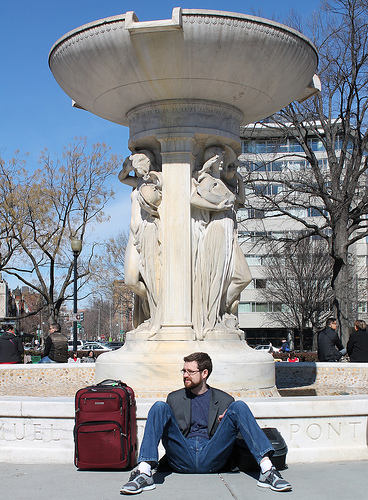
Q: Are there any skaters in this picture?
A: No, there are no skaters.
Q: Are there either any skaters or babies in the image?
A: No, there are no skaters or babies.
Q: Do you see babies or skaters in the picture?
A: No, there are no skaters or babies.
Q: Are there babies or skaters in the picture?
A: No, there are no skaters or babies.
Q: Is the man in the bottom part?
A: Yes, the man is in the bottom of the image.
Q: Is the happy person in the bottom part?
A: Yes, the man is in the bottom of the image.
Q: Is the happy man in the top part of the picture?
A: No, the man is in the bottom of the image.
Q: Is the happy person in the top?
A: No, the man is in the bottom of the image.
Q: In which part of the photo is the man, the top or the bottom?
A: The man is in the bottom of the image.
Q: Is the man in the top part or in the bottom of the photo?
A: The man is in the bottom of the image.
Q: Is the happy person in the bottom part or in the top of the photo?
A: The man is in the bottom of the image.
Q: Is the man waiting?
A: Yes, the man is waiting.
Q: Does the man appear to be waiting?
A: Yes, the man is waiting.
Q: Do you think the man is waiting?
A: Yes, the man is waiting.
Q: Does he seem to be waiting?
A: Yes, the man is waiting.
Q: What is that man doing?
A: The man is waiting.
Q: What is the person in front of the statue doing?
A: The man is waiting.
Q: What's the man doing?
A: The man is waiting.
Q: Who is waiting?
A: The man is waiting.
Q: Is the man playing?
A: No, the man is waiting.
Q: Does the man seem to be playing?
A: No, the man is waiting.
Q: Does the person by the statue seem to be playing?
A: No, the man is waiting.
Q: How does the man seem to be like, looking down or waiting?
A: The man is waiting.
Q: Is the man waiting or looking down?
A: The man is waiting.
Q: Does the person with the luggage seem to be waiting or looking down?
A: The man is waiting.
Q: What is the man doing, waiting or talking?
A: The man is waiting.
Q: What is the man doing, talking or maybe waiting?
A: The man is waiting.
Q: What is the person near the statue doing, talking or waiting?
A: The man is waiting.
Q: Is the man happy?
A: Yes, the man is happy.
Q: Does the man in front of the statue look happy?
A: Yes, the man is happy.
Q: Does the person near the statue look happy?
A: Yes, the man is happy.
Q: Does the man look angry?
A: No, the man is happy.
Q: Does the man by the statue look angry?
A: No, the man is happy.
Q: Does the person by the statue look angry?
A: No, the man is happy.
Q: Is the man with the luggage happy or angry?
A: The man is happy.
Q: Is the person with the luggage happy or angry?
A: The man is happy.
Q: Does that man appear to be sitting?
A: Yes, the man is sitting.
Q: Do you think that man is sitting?
A: Yes, the man is sitting.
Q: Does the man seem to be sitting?
A: Yes, the man is sitting.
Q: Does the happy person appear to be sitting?
A: Yes, the man is sitting.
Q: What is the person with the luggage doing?
A: The man is sitting.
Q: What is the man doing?
A: The man is sitting.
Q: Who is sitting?
A: The man is sitting.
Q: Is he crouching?
A: No, the man is sitting.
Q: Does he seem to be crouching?
A: No, the man is sitting.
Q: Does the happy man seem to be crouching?
A: No, the man is sitting.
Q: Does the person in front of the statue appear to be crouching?
A: No, the man is sitting.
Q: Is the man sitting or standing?
A: The man is sitting.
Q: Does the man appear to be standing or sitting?
A: The man is sitting.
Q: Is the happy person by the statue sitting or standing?
A: The man is sitting.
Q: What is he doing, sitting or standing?
A: The man is sitting.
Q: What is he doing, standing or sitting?
A: The man is sitting.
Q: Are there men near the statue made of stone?
A: Yes, there is a man near the statue.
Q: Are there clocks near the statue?
A: No, there is a man near the statue.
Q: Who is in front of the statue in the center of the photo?
A: The man is in front of the statue.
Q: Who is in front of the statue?
A: The man is in front of the statue.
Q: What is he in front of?
A: The man is in front of the statue.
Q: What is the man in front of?
A: The man is in front of the statue.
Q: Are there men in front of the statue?
A: Yes, there is a man in front of the statue.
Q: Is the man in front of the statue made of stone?
A: Yes, the man is in front of the statue.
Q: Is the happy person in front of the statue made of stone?
A: Yes, the man is in front of the statue.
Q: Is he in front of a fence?
A: No, the man is in front of the statue.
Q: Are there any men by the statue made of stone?
A: Yes, there is a man by the statue.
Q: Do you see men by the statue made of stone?
A: Yes, there is a man by the statue.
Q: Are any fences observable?
A: No, there are no fences.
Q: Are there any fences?
A: No, there are no fences.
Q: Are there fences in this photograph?
A: No, there are no fences.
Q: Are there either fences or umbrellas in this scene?
A: No, there are no fences or umbrellas.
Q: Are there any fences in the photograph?
A: No, there are no fences.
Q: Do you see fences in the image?
A: No, there are no fences.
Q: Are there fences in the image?
A: No, there are no fences.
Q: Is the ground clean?
A: Yes, the ground is clean.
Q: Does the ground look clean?
A: Yes, the ground is clean.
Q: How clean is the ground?
A: The ground is clean.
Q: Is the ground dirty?
A: No, the ground is clean.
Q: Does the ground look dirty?
A: No, the ground is clean.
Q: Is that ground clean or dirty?
A: The ground is clean.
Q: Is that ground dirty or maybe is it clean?
A: The ground is clean.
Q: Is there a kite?
A: No, there are no kites.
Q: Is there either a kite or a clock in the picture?
A: No, there are no kites or clocks.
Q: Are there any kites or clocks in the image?
A: No, there are no kites or clocks.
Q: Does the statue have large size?
A: Yes, the statue is large.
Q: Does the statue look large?
A: Yes, the statue is large.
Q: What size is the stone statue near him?
A: The statue is large.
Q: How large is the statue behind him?
A: The statue is large.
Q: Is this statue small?
A: No, the statue is large.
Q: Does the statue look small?
A: No, the statue is large.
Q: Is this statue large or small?
A: The statue is large.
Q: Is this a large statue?
A: Yes, this is a large statue.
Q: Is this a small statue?
A: No, this is a large statue.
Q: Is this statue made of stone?
A: Yes, the statue is made of stone.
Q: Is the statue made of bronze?
A: No, the statue is made of stone.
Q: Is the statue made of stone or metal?
A: The statue is made of stone.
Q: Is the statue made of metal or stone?
A: The statue is made of stone.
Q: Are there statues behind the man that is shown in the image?
A: Yes, there is a statue behind the man.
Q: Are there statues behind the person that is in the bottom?
A: Yes, there is a statue behind the man.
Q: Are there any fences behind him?
A: No, there is a statue behind the man.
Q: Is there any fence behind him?
A: No, there is a statue behind the man.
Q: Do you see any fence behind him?
A: No, there is a statue behind the man.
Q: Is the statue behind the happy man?
A: Yes, the statue is behind the man.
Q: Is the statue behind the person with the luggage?
A: Yes, the statue is behind the man.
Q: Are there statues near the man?
A: Yes, there is a statue near the man.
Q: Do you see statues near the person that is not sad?
A: Yes, there is a statue near the man.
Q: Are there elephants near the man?
A: No, there is a statue near the man.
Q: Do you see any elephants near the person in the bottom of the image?
A: No, there is a statue near the man.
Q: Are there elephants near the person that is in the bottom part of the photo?
A: No, there is a statue near the man.